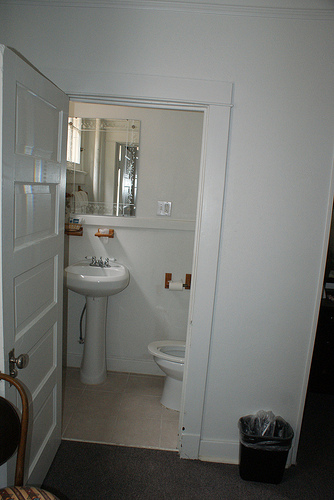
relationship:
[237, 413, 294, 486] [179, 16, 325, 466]
basket against wall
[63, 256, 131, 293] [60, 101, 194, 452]
sink in bathroom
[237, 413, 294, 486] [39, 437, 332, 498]
basket on floor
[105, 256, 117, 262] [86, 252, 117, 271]
knob on sink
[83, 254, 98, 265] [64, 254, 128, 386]
knob on sink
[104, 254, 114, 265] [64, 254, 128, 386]
knob on sink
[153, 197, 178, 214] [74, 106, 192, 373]
outlet on wall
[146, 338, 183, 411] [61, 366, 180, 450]
toilet on floor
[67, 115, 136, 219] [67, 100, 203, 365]
mirror on wall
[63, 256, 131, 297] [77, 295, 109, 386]
sink on stand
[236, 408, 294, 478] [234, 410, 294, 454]
basket with liner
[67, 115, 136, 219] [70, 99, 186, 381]
mirror in bathroom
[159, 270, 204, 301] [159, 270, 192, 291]
paper roll on rack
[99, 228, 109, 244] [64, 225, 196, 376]
cups hanging on wall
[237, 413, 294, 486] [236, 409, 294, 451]
basket with bag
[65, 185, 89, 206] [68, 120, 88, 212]
towel rack hanging on wall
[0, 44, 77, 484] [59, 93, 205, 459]
bathroom door opens to bathroom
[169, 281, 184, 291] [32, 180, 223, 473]
paper roll in bathroom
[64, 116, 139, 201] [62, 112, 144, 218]
reflection in mirror